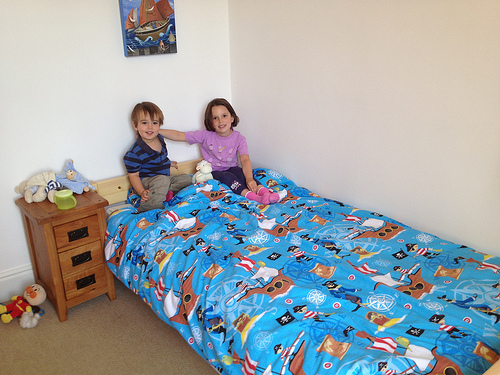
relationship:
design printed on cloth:
[342, 257, 437, 303] [197, 202, 382, 323]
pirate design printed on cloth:
[419, 307, 467, 342] [211, 233, 486, 359]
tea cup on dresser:
[54, 187, 76, 211] [2, 142, 127, 322]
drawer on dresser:
[50, 212, 107, 248] [15, 180, 118, 322]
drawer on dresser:
[50, 238, 109, 278] [15, 180, 118, 322]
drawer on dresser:
[58, 264, 115, 301] [15, 180, 118, 322]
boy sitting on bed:
[123, 101, 191, 212] [79, 159, 497, 371]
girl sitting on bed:
[159, 97, 283, 208] [79, 159, 497, 371]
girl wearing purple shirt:
[159, 97, 283, 208] [184, 126, 252, 172]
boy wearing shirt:
[123, 101, 191, 212] [105, 126, 177, 179]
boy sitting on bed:
[123, 101, 195, 220] [79, 159, 497, 371]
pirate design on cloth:
[427, 313, 475, 338] [132, 166, 473, 371]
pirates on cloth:
[301, 230, 341, 253] [132, 166, 473, 371]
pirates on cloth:
[237, 286, 246, 292] [132, 166, 473, 371]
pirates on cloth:
[392, 267, 409, 274] [132, 166, 473, 371]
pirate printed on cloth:
[288, 244, 313, 263] [100, 164, 497, 372]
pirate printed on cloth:
[293, 303, 330, 324] [100, 164, 497, 372]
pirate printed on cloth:
[193, 235, 220, 257] [100, 164, 497, 372]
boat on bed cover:
[356, 302, 428, 342] [105, 168, 498, 374]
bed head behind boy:
[85, 154, 285, 209] [123, 101, 191, 212]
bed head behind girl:
[85, 154, 285, 209] [159, 97, 283, 208]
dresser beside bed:
[15, 186, 115, 315] [115, 152, 481, 354]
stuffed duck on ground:
[3, 282, 52, 331] [3, 280, 220, 372]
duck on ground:
[3, 282, 43, 331] [3, 280, 220, 372]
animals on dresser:
[8, 157, 100, 209] [14, 195, 118, 313]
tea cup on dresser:
[54, 187, 76, 211] [15, 180, 118, 322]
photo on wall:
[116, 0, 179, 57] [1, 0, 231, 279]